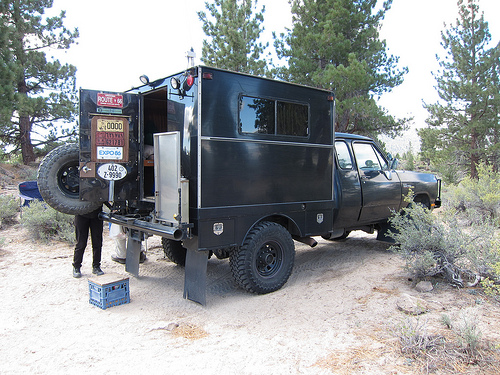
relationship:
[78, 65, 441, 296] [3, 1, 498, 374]
truck in woods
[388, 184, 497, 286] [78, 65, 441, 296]
bush beside truck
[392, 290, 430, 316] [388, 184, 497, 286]
stone beside bush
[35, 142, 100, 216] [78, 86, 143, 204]
tire on door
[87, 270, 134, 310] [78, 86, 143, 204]
crate beside door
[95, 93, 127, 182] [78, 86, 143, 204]
plates on door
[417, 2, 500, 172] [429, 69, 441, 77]
tree with leaves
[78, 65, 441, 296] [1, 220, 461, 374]
truck on road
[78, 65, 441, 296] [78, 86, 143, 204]
truck with door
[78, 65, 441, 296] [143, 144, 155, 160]
truck carrying merchandise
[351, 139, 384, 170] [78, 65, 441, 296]
window on truck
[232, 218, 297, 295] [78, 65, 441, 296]
wheel on truck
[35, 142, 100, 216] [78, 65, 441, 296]
tire on truck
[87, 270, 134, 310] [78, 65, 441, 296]
crate behind truck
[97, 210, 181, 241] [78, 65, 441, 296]
pipe on truck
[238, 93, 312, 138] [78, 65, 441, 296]
windows on truck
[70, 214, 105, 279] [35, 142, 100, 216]
legs behind spare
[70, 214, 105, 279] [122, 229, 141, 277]
legs behind flap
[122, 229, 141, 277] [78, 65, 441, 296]
mudflap of truck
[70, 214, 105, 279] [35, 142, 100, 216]
legs under tire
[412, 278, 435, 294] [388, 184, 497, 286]
rock by bush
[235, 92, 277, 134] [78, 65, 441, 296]
window on truck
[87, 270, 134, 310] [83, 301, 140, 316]
crate on ground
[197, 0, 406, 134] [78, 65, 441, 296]
trees behind truck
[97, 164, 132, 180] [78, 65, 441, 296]
logo on truck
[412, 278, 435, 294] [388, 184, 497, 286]
rock next to shrubbery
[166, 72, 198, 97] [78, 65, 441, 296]
lights on truck